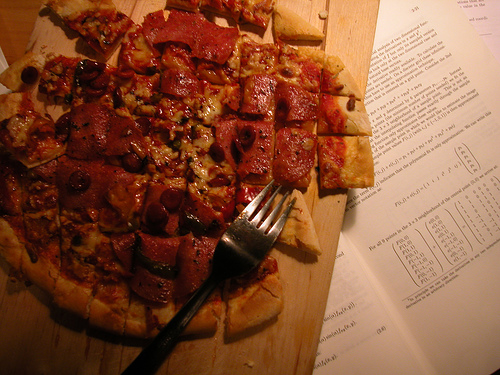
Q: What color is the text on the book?
A: Black.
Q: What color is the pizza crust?
A: Brown.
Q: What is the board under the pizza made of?
A: Wood.